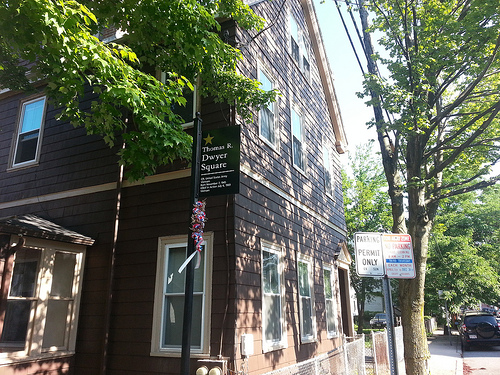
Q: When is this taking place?
A: Daytime.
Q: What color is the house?
A: Brown.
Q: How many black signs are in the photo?
A: One.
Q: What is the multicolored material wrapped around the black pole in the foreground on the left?
A: Bow.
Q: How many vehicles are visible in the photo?
A: One.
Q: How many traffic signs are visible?
A: Two.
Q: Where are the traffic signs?
A: Sidewalk.